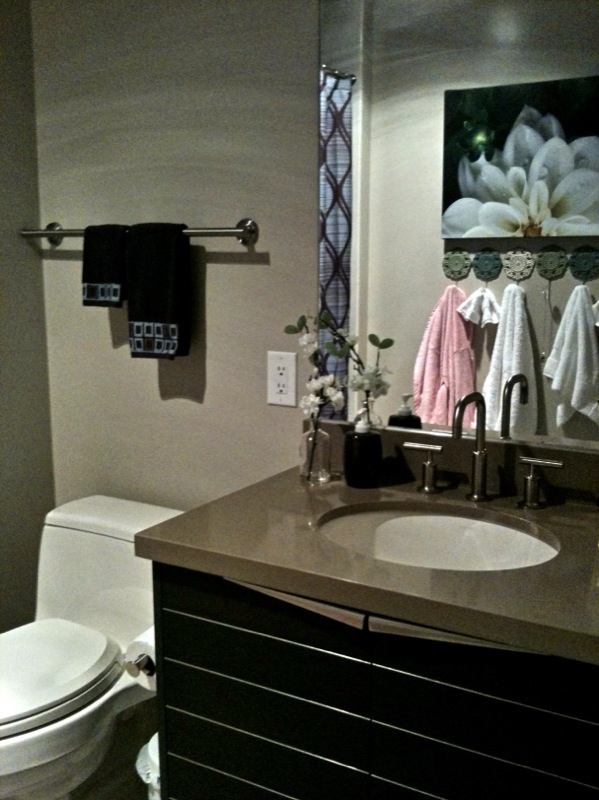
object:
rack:
[14, 210, 274, 275]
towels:
[14, 210, 274, 333]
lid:
[19, 618, 130, 724]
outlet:
[251, 345, 325, 424]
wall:
[93, 121, 325, 423]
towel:
[552, 279, 593, 393]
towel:
[469, 283, 555, 423]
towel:
[383, 252, 492, 354]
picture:
[441, 116, 585, 211]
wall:
[358, 1, 586, 211]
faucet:
[433, 412, 531, 519]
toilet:
[32, 496, 257, 694]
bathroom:
[35, 114, 593, 685]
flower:
[311, 341, 408, 439]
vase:
[339, 432, 393, 489]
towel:
[119, 217, 201, 367]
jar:
[294, 410, 336, 488]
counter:
[166, 438, 584, 695]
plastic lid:
[427, 247, 583, 286]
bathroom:
[2, 2, 596, 793]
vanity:
[128, 411, 597, 796]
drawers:
[370, 658, 598, 795]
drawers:
[155, 656, 371, 774]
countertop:
[135, 410, 597, 664]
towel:
[477, 286, 538, 368]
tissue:
[127, 624, 156, 689]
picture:
[441, 70, 597, 253]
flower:
[442, 105, 597, 235]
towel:
[78, 224, 119, 292]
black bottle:
[345, 427, 381, 489]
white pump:
[355, 405, 371, 435]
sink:
[317, 502, 563, 572]